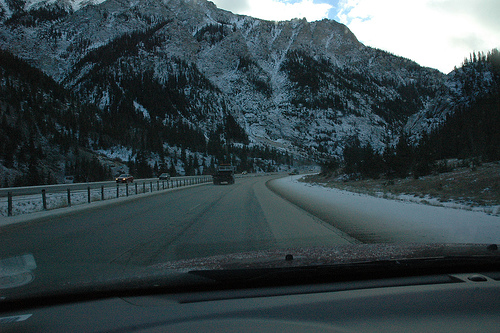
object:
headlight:
[115, 178, 119, 180]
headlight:
[122, 178, 125, 180]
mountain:
[3, 2, 275, 191]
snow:
[271, 65, 279, 76]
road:
[1, 166, 361, 288]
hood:
[195, 253, 475, 288]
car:
[213, 166, 236, 186]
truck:
[198, 154, 247, 198]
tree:
[178, 74, 188, 94]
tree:
[241, 158, 253, 172]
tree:
[142, 70, 150, 108]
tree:
[154, 86, 172, 116]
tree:
[208, 128, 223, 155]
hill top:
[82, 46, 209, 80]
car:
[159, 173, 170, 181]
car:
[116, 174, 134, 183]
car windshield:
[0, 2, 496, 301]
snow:
[378, 170, 497, 214]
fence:
[0, 175, 212, 224]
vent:
[170, 276, 471, 305]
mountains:
[63, 45, 254, 143]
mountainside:
[399, 52, 496, 141]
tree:
[472, 51, 477, 63]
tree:
[487, 50, 492, 62]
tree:
[481, 51, 487, 68]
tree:
[476, 51, 481, 63]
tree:
[463, 57, 469, 69]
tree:
[454, 65, 459, 75]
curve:
[263, 172, 325, 209]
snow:
[271, 94, 307, 130]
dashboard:
[0, 269, 500, 333]